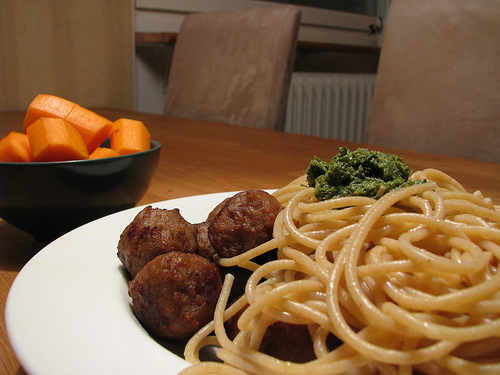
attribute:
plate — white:
[2, 178, 207, 373]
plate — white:
[3, 187, 499, 374]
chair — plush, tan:
[164, 19, 314, 124]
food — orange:
[2, 92, 152, 160]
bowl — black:
[0, 132, 161, 243]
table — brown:
[181, 127, 299, 172]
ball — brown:
[203, 187, 280, 263]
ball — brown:
[112, 205, 198, 280]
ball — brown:
[130, 253, 227, 342]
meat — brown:
[222, 205, 261, 233]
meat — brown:
[137, 222, 174, 247]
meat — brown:
[147, 265, 203, 305]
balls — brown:
[118, 184, 289, 346]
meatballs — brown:
[108, 181, 278, 341]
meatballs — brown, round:
[120, 247, 237, 347]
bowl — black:
[0, 172, 117, 212]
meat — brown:
[140, 259, 202, 322]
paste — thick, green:
[303, 132, 424, 205]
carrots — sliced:
[1, 86, 148, 166]